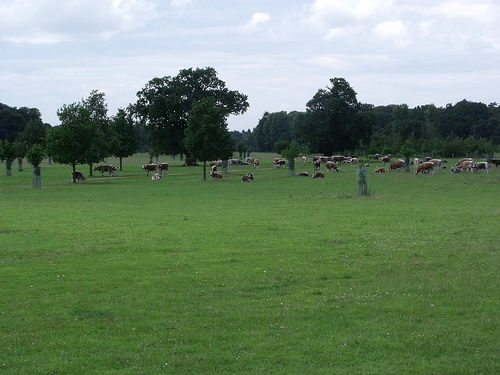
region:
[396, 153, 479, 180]
cows in a field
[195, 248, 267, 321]
the green grass of a field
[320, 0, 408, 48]
clouds in the sky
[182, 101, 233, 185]
a tree in a field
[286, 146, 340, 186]
cows under a tree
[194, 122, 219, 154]
the leaves of a tree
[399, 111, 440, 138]
the leaves of trees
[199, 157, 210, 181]
the trunk of a tree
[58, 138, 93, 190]
a cow under a tree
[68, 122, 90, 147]
the leaves of a tree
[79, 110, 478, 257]
animals in a field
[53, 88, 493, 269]
animals in a green field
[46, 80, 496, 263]
animals in a grass field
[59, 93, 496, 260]
animals in a green grass field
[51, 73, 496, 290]
cows in a field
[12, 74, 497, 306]
cows in a grass field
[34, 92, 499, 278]
cows in a green grass field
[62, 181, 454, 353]
a green grass field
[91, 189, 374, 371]
a field of green grass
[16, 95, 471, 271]
a field of animals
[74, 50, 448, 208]
Trees in the background.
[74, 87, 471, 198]
Animals on the grass.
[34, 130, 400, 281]
Grass on the field.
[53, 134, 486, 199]
Trunks of the trees.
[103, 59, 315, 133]
Blue sky in the background.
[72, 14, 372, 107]
White clouds in the blue sky.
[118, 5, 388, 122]
Blue sky with white clouds.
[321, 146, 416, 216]
plant on the grass.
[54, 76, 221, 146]
Leaves on the tree.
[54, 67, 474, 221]
Several trees in the background.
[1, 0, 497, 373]
A large green field.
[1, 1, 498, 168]
Blue skies with white puffy clouds.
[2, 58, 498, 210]
A bunch of green trees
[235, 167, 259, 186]
A single cow laying down.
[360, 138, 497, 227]
Cows grazing in the field.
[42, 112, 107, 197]
cow standing next to the tree.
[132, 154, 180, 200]
two cows walking and one laying down on the grass.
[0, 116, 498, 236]
Herd of cows grazing in the field.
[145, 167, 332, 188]
Five cows laying on the grass.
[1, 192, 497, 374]
Green grass with some weeds growing.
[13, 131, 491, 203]
Several cows are together.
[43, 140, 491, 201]
The cows are grazing.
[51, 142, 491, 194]
The cows are brown and tan.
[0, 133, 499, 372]
The cows are in a field.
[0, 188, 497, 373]
The field is green.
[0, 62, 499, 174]
Trees are on the edge of the field.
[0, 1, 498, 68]
Clouds are in the sky.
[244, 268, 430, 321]
Small flowers grow in the grass.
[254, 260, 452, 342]
The flowers are white.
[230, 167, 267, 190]
The cow is sitting in the grass.